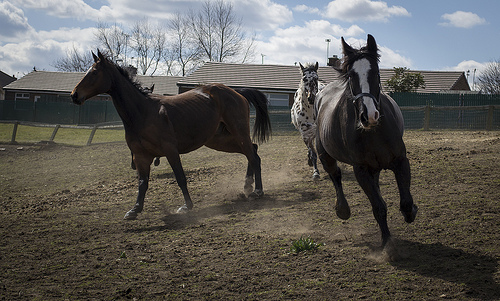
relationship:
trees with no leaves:
[48, 6, 267, 72] [54, 4, 271, 82]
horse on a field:
[67, 47, 274, 224] [6, 119, 494, 297]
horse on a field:
[290, 59, 336, 182] [6, 119, 494, 297]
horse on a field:
[311, 32, 415, 266] [6, 119, 494, 297]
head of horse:
[336, 32, 380, 137] [308, 37, 418, 249]